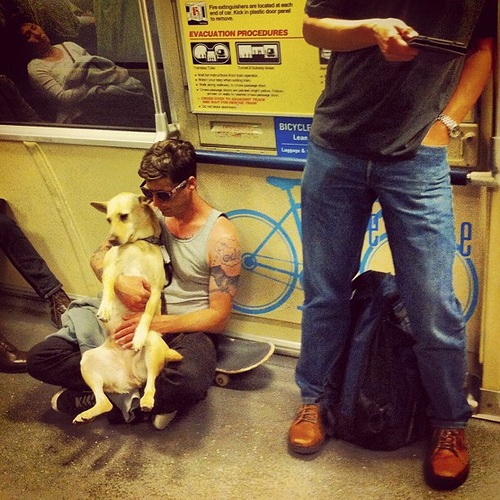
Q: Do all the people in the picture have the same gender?
A: No, they are both male and female.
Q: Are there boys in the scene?
A: No, there are no boys.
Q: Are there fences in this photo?
A: No, there are no fences.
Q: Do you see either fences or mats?
A: No, there are no fences or mats.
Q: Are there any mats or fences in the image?
A: No, there are no fences or mats.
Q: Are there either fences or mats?
A: No, there are no fences or mats.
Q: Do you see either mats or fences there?
A: No, there are no fences or mats.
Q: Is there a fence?
A: No, there are no fences.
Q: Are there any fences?
A: No, there are no fences.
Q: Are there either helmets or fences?
A: No, there are no fences or helmets.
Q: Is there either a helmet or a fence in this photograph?
A: No, there are no fences or helmets.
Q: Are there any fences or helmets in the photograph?
A: No, there are no fences or helmets.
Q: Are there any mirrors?
A: No, there are no mirrors.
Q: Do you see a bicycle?
A: Yes, there is a bicycle.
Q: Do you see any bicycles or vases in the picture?
A: Yes, there is a bicycle.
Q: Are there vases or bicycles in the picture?
A: Yes, there is a bicycle.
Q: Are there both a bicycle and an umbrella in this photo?
A: No, there is a bicycle but no umbrellas.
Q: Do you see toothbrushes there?
A: No, there are no toothbrushes.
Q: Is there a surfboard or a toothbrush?
A: No, there are no toothbrushes or surfboards.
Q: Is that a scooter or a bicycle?
A: That is a bicycle.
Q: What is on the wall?
A: The bicycle is on the wall.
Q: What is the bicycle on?
A: The bicycle is on the wall.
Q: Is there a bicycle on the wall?
A: Yes, there is a bicycle on the wall.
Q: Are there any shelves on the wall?
A: No, there is a bicycle on the wall.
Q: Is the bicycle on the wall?
A: Yes, the bicycle is on the wall.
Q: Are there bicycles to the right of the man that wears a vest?
A: Yes, there is a bicycle to the right of the man.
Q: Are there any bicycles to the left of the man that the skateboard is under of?
A: No, the bicycle is to the right of the man.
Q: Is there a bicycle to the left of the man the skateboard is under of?
A: No, the bicycle is to the right of the man.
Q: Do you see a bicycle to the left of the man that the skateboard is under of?
A: No, the bicycle is to the right of the man.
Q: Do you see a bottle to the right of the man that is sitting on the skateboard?
A: No, there is a bicycle to the right of the man.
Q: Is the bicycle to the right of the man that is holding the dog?
A: Yes, the bicycle is to the right of the man.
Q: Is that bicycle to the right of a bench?
A: No, the bicycle is to the right of the man.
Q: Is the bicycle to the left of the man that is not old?
A: No, the bicycle is to the right of the man.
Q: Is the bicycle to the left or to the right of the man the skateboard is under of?
A: The bicycle is to the right of the man.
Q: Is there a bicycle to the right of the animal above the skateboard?
A: Yes, there is a bicycle to the right of the dog.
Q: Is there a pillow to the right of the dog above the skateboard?
A: No, there is a bicycle to the right of the dog.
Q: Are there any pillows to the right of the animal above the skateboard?
A: No, there is a bicycle to the right of the dog.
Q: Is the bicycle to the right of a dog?
A: Yes, the bicycle is to the right of a dog.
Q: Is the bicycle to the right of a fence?
A: No, the bicycle is to the right of a dog.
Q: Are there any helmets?
A: No, there are no helmets.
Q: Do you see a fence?
A: No, there are no fences.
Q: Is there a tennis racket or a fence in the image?
A: No, there are no fences or rackets.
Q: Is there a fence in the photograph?
A: No, there are no fences.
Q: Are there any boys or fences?
A: No, there are no fences or boys.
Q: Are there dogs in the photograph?
A: Yes, there is a dog.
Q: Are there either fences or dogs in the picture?
A: Yes, there is a dog.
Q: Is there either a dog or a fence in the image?
A: Yes, there is a dog.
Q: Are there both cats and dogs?
A: No, there is a dog but no cats.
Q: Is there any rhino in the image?
A: No, there are no rhinos.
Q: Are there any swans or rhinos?
A: No, there are no rhinos or swans.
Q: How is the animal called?
A: The animal is a dog.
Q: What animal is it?
A: The animal is a dog.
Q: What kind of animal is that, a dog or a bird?
A: This is a dog.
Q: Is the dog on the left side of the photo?
A: Yes, the dog is on the left of the image.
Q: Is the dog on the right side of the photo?
A: No, the dog is on the left of the image.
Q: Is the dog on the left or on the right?
A: The dog is on the left of the image.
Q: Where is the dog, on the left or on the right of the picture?
A: The dog is on the left of the image.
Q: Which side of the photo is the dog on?
A: The dog is on the left of the image.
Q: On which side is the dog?
A: The dog is on the left of the image.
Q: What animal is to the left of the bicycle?
A: The animal is a dog.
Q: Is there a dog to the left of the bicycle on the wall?
A: Yes, there is a dog to the left of the bicycle.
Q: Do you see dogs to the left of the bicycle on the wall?
A: Yes, there is a dog to the left of the bicycle.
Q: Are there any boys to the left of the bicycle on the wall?
A: No, there is a dog to the left of the bicycle.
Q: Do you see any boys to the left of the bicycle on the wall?
A: No, there is a dog to the left of the bicycle.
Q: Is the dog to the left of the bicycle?
A: Yes, the dog is to the left of the bicycle.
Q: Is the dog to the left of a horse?
A: No, the dog is to the left of the bicycle.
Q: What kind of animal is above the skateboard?
A: The animal is a dog.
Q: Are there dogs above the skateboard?
A: Yes, there is a dog above the skateboard.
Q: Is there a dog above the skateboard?
A: Yes, there is a dog above the skateboard.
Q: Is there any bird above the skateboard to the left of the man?
A: No, there is a dog above the skateboard.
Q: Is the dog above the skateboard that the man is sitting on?
A: Yes, the dog is above the skateboard.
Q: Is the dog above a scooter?
A: No, the dog is above the skateboard.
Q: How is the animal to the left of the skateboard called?
A: The animal is a dog.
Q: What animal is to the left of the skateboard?
A: The animal is a dog.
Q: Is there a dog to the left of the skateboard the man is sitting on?
A: Yes, there is a dog to the left of the skateboard.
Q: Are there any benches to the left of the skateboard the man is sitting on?
A: No, there is a dog to the left of the skateboard.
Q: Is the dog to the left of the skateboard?
A: Yes, the dog is to the left of the skateboard.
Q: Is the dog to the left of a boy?
A: No, the dog is to the left of the skateboard.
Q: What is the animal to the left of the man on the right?
A: The animal is a dog.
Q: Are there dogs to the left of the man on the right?
A: Yes, there is a dog to the left of the man.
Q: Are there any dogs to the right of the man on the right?
A: No, the dog is to the left of the man.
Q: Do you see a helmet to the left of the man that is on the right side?
A: No, there is a dog to the left of the man.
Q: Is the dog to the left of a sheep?
A: No, the dog is to the left of the man.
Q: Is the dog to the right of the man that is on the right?
A: No, the dog is to the left of the man.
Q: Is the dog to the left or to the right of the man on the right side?
A: The dog is to the left of the man.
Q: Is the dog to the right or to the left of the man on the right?
A: The dog is to the left of the man.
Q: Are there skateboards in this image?
A: Yes, there is a skateboard.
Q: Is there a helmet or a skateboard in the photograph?
A: Yes, there is a skateboard.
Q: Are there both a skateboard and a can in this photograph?
A: No, there is a skateboard but no cans.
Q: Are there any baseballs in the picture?
A: No, there are no baseballs.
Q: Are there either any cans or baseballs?
A: No, there are no baseballs or cans.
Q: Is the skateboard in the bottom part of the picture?
A: Yes, the skateboard is in the bottom of the image.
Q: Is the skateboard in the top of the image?
A: No, the skateboard is in the bottom of the image.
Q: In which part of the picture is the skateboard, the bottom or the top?
A: The skateboard is in the bottom of the image.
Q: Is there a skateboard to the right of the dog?
A: Yes, there is a skateboard to the right of the dog.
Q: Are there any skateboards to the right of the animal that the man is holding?
A: Yes, there is a skateboard to the right of the dog.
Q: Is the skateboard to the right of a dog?
A: Yes, the skateboard is to the right of a dog.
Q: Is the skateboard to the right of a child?
A: No, the skateboard is to the right of a dog.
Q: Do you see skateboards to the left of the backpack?
A: Yes, there is a skateboard to the left of the backpack.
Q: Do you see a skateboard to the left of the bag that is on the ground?
A: Yes, there is a skateboard to the left of the backpack.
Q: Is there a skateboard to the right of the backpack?
A: No, the skateboard is to the left of the backpack.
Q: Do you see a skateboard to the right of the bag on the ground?
A: No, the skateboard is to the left of the backpack.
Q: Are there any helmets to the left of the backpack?
A: No, there is a skateboard to the left of the backpack.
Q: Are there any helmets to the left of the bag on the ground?
A: No, there is a skateboard to the left of the backpack.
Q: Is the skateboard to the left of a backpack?
A: Yes, the skateboard is to the left of a backpack.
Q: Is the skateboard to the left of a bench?
A: No, the skateboard is to the left of a backpack.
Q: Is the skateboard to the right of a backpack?
A: No, the skateboard is to the left of a backpack.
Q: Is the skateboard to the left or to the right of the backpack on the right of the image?
A: The skateboard is to the left of the backpack.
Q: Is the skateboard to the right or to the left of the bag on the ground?
A: The skateboard is to the left of the backpack.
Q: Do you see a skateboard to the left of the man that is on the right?
A: Yes, there is a skateboard to the left of the man.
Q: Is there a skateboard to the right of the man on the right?
A: No, the skateboard is to the left of the man.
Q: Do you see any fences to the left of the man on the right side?
A: No, there is a skateboard to the left of the man.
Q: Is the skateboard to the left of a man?
A: Yes, the skateboard is to the left of a man.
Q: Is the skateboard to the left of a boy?
A: No, the skateboard is to the left of a man.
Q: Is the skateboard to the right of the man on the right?
A: No, the skateboard is to the left of the man.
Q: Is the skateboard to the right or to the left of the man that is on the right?
A: The skateboard is to the left of the man.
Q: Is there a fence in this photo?
A: No, there are no fences.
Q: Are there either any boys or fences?
A: No, there are no fences or boys.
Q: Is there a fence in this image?
A: No, there are no fences.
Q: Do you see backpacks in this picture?
A: Yes, there is a backpack.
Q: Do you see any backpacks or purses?
A: Yes, there is a backpack.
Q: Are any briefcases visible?
A: No, there are no briefcases.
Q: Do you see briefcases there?
A: No, there are no briefcases.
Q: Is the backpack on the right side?
A: Yes, the backpack is on the right of the image.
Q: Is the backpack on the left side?
A: No, the backpack is on the right of the image.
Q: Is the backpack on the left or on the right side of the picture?
A: The backpack is on the right of the image.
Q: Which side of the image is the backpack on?
A: The backpack is on the right of the image.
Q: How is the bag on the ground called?
A: The bag is a backpack.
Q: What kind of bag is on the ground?
A: The bag is a backpack.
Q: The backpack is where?
A: The backpack is on the ground.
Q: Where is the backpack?
A: The backpack is on the ground.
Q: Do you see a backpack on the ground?
A: Yes, there is a backpack on the ground.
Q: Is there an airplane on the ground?
A: No, there is a backpack on the ground.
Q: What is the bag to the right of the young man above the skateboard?
A: The bag is a backpack.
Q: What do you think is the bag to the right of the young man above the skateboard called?
A: The bag is a backpack.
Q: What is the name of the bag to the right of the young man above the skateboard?
A: The bag is a backpack.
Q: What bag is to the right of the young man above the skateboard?
A: The bag is a backpack.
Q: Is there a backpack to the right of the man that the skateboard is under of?
A: Yes, there is a backpack to the right of the man.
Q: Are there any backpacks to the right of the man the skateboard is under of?
A: Yes, there is a backpack to the right of the man.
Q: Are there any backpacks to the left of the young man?
A: No, the backpack is to the right of the man.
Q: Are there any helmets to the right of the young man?
A: No, there is a backpack to the right of the man.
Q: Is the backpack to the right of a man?
A: Yes, the backpack is to the right of a man.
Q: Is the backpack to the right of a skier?
A: No, the backpack is to the right of a man.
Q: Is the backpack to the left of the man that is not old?
A: No, the backpack is to the right of the man.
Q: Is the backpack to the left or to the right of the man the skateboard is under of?
A: The backpack is to the right of the man.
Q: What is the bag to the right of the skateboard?
A: The bag is a backpack.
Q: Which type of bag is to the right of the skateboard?
A: The bag is a backpack.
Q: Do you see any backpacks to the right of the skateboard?
A: Yes, there is a backpack to the right of the skateboard.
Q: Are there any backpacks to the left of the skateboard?
A: No, the backpack is to the right of the skateboard.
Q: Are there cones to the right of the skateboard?
A: No, there is a backpack to the right of the skateboard.